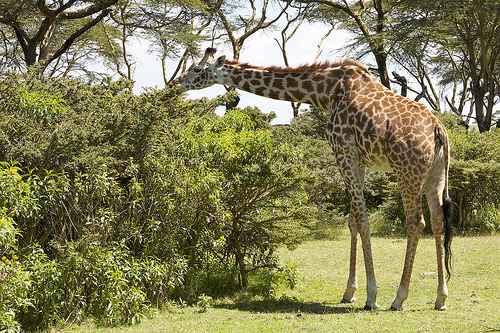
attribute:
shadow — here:
[208, 293, 365, 320]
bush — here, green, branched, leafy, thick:
[1, 64, 304, 331]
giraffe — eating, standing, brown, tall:
[170, 46, 454, 311]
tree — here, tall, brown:
[3, 1, 127, 85]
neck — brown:
[216, 60, 335, 107]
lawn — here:
[142, 208, 494, 322]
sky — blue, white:
[2, 0, 474, 129]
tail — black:
[435, 123, 456, 283]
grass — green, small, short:
[102, 223, 490, 332]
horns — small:
[198, 46, 218, 60]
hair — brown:
[227, 57, 357, 75]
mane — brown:
[222, 57, 373, 72]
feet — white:
[341, 291, 374, 313]